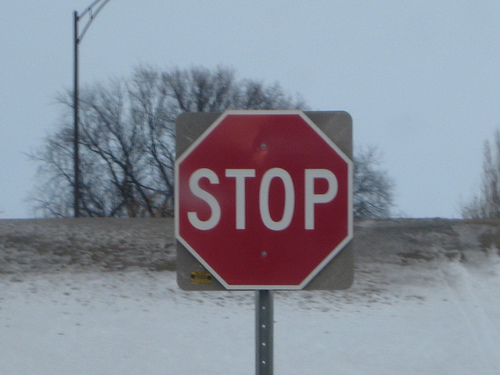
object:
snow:
[1, 270, 496, 375]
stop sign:
[176, 110, 351, 289]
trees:
[27, 66, 398, 220]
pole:
[254, 287, 275, 374]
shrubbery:
[458, 126, 499, 249]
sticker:
[189, 272, 216, 283]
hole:
[261, 305, 266, 312]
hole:
[260, 341, 266, 347]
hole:
[261, 323, 268, 330]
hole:
[260, 359, 269, 365]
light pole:
[74, 0, 110, 221]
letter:
[186, 167, 220, 231]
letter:
[224, 168, 256, 232]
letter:
[259, 167, 295, 232]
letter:
[303, 168, 338, 231]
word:
[187, 166, 338, 229]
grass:
[1, 220, 175, 276]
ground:
[1, 215, 498, 374]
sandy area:
[351, 217, 435, 271]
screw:
[259, 142, 268, 149]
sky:
[4, 2, 498, 217]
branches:
[161, 68, 192, 111]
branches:
[211, 63, 234, 107]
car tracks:
[432, 248, 500, 374]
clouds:
[3, 0, 496, 121]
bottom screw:
[263, 251, 268, 256]